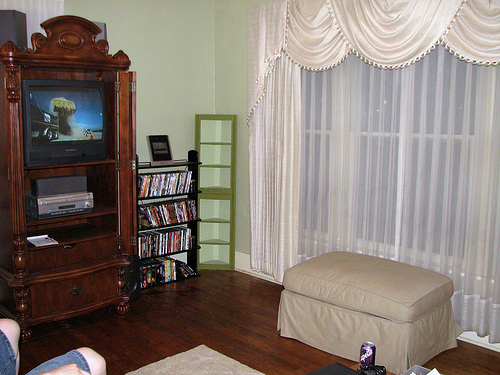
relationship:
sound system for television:
[26, 176, 112, 223] [18, 74, 113, 164]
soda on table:
[358, 340, 380, 367] [315, 353, 409, 374]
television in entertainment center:
[18, 74, 113, 164] [3, 13, 152, 341]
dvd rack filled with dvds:
[137, 155, 204, 294] [154, 170, 184, 196]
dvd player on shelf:
[32, 196, 93, 218] [18, 207, 118, 229]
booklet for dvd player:
[25, 229, 58, 256] [32, 196, 93, 218]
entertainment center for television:
[3, 13, 152, 341] [18, 74, 113, 164]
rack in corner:
[192, 109, 244, 273] [204, 44, 230, 90]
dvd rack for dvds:
[137, 155, 204, 294] [154, 170, 184, 196]